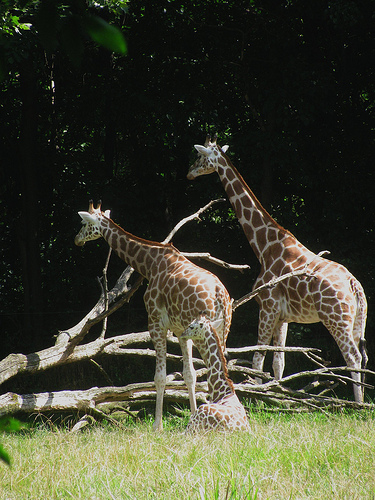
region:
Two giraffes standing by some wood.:
[69, 130, 370, 428]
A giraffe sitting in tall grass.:
[178, 312, 254, 446]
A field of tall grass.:
[0, 405, 373, 499]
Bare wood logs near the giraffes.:
[0, 194, 373, 422]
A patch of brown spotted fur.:
[320, 276, 343, 314]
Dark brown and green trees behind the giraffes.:
[3, 1, 373, 331]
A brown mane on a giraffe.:
[214, 141, 302, 240]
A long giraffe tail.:
[350, 277, 369, 392]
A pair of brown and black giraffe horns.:
[86, 194, 102, 214]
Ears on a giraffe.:
[193, 137, 231, 158]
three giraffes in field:
[75, 120, 357, 454]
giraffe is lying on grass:
[166, 325, 254, 462]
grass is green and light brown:
[27, 424, 358, 497]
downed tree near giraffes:
[26, 289, 362, 461]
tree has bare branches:
[4, 295, 339, 443]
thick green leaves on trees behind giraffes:
[18, 15, 373, 279]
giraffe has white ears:
[72, 209, 118, 225]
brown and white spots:
[114, 227, 217, 324]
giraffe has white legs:
[138, 341, 208, 449]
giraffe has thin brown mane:
[110, 219, 185, 254]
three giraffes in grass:
[66, 129, 373, 441]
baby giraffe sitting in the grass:
[171, 309, 256, 450]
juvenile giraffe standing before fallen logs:
[64, 187, 240, 433]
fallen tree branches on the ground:
[1, 194, 373, 437]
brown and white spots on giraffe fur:
[158, 262, 190, 304]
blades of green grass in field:
[202, 467, 273, 498]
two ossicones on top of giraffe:
[201, 128, 222, 144]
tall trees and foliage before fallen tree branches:
[1, 3, 371, 405]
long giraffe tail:
[350, 277, 369, 391]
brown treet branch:
[230, 341, 331, 372]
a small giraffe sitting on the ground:
[177, 318, 262, 443]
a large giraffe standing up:
[181, 134, 372, 405]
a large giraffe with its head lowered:
[61, 201, 236, 439]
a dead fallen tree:
[13, 251, 372, 464]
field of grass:
[61, 451, 325, 498]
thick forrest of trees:
[20, 101, 157, 327]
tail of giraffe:
[344, 281, 372, 388]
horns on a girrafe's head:
[80, 196, 109, 222]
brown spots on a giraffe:
[162, 274, 210, 315]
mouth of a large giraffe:
[181, 165, 205, 185]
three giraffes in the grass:
[47, 117, 370, 469]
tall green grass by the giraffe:
[105, 443, 356, 490]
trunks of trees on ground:
[14, 337, 154, 421]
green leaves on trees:
[249, 14, 364, 162]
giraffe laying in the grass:
[163, 309, 259, 453]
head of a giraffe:
[183, 133, 228, 179]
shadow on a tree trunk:
[18, 346, 43, 416]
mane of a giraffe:
[205, 322, 239, 395]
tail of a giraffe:
[350, 288, 373, 369]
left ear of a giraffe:
[76, 209, 91, 225]